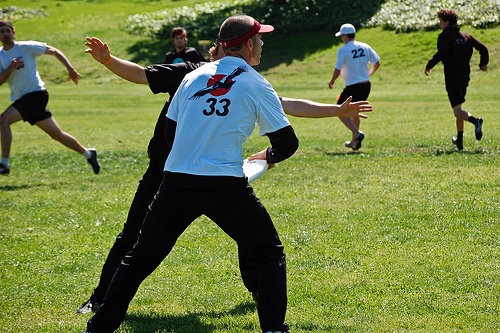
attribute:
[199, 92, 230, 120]
33 — black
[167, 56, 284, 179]
shirt — white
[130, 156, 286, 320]
pants — black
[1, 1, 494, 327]
grass — green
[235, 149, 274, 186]
frisbee — white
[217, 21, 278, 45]
visor — red, maroon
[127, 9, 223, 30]
flowers — white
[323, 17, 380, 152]
player 22 — running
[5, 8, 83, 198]
person — running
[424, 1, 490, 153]
person — playing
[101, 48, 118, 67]
bracelet — orange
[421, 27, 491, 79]
shirt — black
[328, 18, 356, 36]
ballcap — white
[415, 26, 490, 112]
clothes — dark